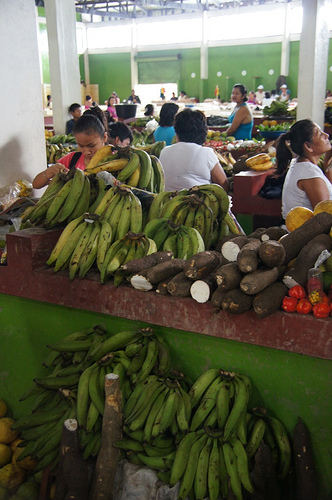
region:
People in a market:
[3, 36, 330, 218]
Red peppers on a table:
[280, 274, 330, 336]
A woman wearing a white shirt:
[270, 101, 330, 251]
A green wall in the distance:
[72, 47, 330, 106]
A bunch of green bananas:
[29, 151, 242, 285]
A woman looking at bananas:
[25, 101, 161, 220]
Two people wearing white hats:
[253, 78, 293, 112]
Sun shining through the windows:
[79, 0, 319, 53]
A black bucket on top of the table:
[109, 94, 158, 131]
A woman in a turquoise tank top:
[217, 70, 262, 161]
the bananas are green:
[130, 358, 209, 478]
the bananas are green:
[167, 364, 221, 495]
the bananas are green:
[127, 383, 174, 484]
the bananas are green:
[152, 416, 195, 494]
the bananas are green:
[157, 407, 180, 447]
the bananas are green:
[137, 366, 185, 461]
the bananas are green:
[164, 449, 199, 494]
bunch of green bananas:
[167, 428, 241, 493]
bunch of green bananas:
[132, 376, 187, 437]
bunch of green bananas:
[196, 357, 244, 435]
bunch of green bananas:
[59, 213, 103, 277]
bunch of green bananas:
[104, 183, 140, 227]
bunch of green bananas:
[154, 218, 196, 255]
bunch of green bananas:
[168, 195, 219, 223]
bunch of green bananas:
[49, 177, 89, 206]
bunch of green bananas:
[70, 321, 99, 347]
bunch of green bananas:
[188, 179, 222, 208]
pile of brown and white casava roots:
[118, 210, 331, 323]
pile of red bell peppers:
[281, 276, 330, 323]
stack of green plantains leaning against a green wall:
[10, 316, 297, 499]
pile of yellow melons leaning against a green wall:
[0, 393, 40, 498]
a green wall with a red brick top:
[1, 225, 331, 498]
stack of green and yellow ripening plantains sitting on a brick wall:
[26, 140, 245, 299]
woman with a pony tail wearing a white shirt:
[269, 118, 331, 232]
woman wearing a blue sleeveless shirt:
[221, 83, 255, 144]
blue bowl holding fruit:
[254, 118, 288, 142]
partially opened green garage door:
[131, 53, 184, 99]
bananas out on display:
[16, 138, 263, 318]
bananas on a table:
[16, 123, 246, 300]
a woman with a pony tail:
[260, 84, 328, 197]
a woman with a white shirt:
[154, 97, 223, 195]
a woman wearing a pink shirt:
[42, 82, 137, 199]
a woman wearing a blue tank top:
[212, 69, 268, 151]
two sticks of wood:
[16, 354, 172, 495]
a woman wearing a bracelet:
[26, 92, 134, 188]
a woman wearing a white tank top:
[262, 85, 328, 230]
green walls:
[47, 18, 330, 112]